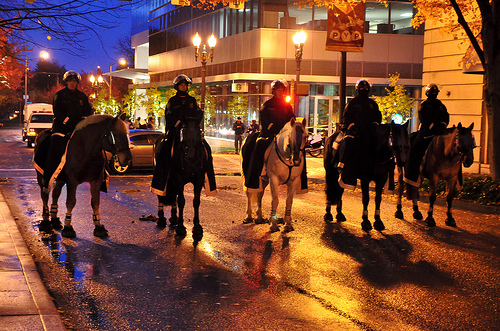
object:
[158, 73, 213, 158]
officers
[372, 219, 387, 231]
hoof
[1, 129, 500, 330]
road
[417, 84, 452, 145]
police officer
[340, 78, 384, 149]
police officer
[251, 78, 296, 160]
police officer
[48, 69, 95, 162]
police officer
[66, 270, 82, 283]
water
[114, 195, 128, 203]
water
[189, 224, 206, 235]
hoof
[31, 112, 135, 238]
horse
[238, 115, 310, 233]
horse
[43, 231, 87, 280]
water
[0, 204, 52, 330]
line